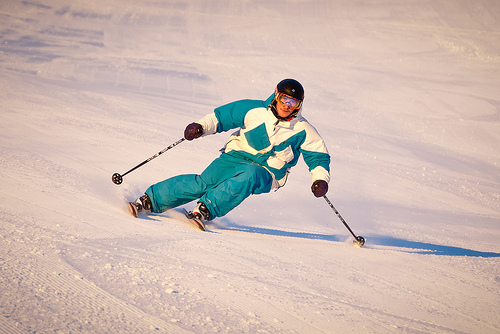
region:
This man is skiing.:
[59, 28, 428, 250]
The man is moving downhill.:
[90, 42, 376, 267]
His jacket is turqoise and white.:
[157, 83, 301, 229]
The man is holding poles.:
[121, 98, 361, 245]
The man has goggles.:
[262, 84, 307, 117]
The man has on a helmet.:
[272, 55, 315, 100]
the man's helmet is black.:
[268, 81, 306, 100]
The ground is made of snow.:
[20, 226, 370, 326]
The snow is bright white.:
[38, 29, 453, 284]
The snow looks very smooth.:
[30, 31, 471, 81]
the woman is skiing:
[148, 43, 410, 223]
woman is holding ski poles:
[97, 56, 484, 310]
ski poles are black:
[81, 99, 393, 289]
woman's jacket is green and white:
[176, 33, 341, 173]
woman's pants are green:
[141, 128, 301, 262]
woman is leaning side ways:
[114, 23, 360, 234]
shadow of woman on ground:
[243, 223, 486, 283]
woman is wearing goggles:
[271, 93, 319, 118]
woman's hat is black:
[248, 67, 338, 107]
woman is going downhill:
[115, 28, 395, 292]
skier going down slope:
[110, 70, 368, 250]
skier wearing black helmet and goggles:
[270, 66, 300, 121]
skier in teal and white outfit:
[145, 76, 330, 227]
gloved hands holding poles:
[110, 120, 366, 250]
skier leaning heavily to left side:
[130, 75, 330, 235]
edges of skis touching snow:
[125, 197, 205, 229]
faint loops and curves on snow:
[341, 15, 491, 130]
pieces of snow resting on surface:
[12, 226, 259, 326]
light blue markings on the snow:
[2, 10, 207, 96]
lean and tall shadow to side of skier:
[228, 212, 493, 265]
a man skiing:
[107, 76, 364, 246]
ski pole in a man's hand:
[310, 176, 367, 241]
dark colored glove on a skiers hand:
[310, 176, 326, 192]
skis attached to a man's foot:
[177, 197, 207, 232]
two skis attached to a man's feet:
[125, 190, 210, 226]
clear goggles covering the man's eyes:
[273, 92, 302, 107]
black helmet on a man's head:
[277, 78, 304, 99]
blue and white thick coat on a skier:
[196, 94, 338, 189]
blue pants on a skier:
[146, 151, 277, 218]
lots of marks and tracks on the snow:
[3, 248, 498, 333]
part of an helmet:
[286, 83, 296, 104]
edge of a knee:
[216, 183, 223, 194]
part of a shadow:
[405, 231, 430, 252]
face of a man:
[268, 89, 298, 135]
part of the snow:
[41, 141, 76, 186]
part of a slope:
[357, 61, 384, 97]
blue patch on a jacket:
[256, 118, 263, 136]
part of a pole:
[346, 217, 357, 239]